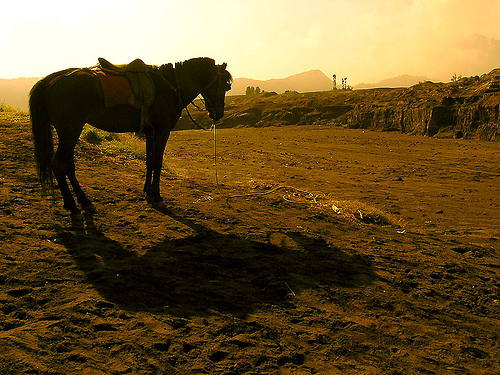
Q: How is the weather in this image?
A: It is cloudy.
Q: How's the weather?
A: It is cloudy.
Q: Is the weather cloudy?
A: Yes, it is cloudy.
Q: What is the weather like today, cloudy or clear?
A: It is cloudy.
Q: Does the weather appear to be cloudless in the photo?
A: No, it is cloudy.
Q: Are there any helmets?
A: No, there are no helmets.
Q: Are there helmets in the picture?
A: No, there are no helmets.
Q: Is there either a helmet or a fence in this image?
A: No, there are no helmets or fences.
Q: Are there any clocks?
A: No, there are no clocks.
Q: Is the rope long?
A: Yes, the rope is long.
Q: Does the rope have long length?
A: Yes, the rope is long.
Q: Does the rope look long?
A: Yes, the rope is long.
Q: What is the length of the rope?
A: The rope is long.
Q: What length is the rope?
A: The rope is long.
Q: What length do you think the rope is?
A: The rope is long.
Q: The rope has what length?
A: The rope is long.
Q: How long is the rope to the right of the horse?
A: The rope is long.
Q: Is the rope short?
A: No, the rope is long.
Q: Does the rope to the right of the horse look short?
A: No, the rope is long.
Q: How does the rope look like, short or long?
A: The rope is long.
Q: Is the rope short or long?
A: The rope is long.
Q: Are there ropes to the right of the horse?
A: Yes, there is a rope to the right of the horse.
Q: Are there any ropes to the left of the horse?
A: No, the rope is to the right of the horse.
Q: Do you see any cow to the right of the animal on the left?
A: No, there is a rope to the right of the horse.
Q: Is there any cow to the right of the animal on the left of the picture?
A: No, there is a rope to the right of the horse.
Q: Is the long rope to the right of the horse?
A: Yes, the rope is to the right of the horse.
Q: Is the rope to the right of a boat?
A: No, the rope is to the right of the horse.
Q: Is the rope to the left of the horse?
A: No, the rope is to the right of the horse.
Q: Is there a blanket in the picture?
A: Yes, there is a blanket.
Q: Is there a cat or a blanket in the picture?
A: Yes, there is a blanket.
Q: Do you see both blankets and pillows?
A: No, there is a blanket but no pillows.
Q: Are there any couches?
A: No, there are no couches.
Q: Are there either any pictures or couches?
A: No, there are no couches or pictures.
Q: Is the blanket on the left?
A: Yes, the blanket is on the left of the image.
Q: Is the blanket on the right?
A: No, the blanket is on the left of the image.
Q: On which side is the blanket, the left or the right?
A: The blanket is on the left of the image.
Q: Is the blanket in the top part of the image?
A: Yes, the blanket is in the top of the image.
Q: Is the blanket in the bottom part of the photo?
A: No, the blanket is in the top of the image.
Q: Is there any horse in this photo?
A: Yes, there is a horse.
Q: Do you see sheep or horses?
A: Yes, there is a horse.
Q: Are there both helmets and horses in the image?
A: No, there is a horse but no helmets.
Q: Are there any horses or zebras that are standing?
A: Yes, the horse is standing.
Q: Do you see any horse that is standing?
A: Yes, there is a horse that is standing.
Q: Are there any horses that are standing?
A: Yes, there is a horse that is standing.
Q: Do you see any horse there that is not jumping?
A: Yes, there is a horse that is standing .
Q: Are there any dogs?
A: No, there are no dogs.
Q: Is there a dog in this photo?
A: No, there are no dogs.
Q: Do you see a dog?
A: No, there are no dogs.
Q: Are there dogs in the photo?
A: No, there are no dogs.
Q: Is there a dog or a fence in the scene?
A: No, there are no dogs or fences.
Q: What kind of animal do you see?
A: The animal is a horse.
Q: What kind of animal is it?
A: The animal is a horse.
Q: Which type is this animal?
A: That is a horse.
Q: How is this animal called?
A: That is a horse.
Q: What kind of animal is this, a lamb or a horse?
A: That is a horse.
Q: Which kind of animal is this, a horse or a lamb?
A: That is a horse.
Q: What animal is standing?
A: The animal is a horse.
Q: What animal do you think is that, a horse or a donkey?
A: That is a horse.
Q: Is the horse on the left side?
A: Yes, the horse is on the left of the image.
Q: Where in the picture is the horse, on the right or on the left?
A: The horse is on the left of the image.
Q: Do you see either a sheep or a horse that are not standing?
A: No, there is a horse but it is standing.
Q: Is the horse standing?
A: Yes, the horse is standing.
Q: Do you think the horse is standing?
A: Yes, the horse is standing.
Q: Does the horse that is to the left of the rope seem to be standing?
A: Yes, the horse is standing.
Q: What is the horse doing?
A: The horse is standing.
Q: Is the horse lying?
A: No, the horse is standing.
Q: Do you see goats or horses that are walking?
A: No, there is a horse but it is standing.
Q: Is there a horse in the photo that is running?
A: No, there is a horse but it is standing.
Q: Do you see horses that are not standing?
A: No, there is a horse but it is standing.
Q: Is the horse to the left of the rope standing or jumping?
A: The horse is standing.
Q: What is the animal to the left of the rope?
A: The animal is a horse.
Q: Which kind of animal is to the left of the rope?
A: The animal is a horse.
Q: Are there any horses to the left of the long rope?
A: Yes, there is a horse to the left of the rope.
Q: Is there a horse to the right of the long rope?
A: No, the horse is to the left of the rope.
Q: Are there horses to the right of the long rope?
A: No, the horse is to the left of the rope.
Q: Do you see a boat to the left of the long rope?
A: No, there is a horse to the left of the rope.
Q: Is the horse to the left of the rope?
A: Yes, the horse is to the left of the rope.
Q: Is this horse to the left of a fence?
A: No, the horse is to the left of the rope.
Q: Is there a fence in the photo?
A: No, there are no fences.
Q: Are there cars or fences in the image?
A: No, there are no fences or cars.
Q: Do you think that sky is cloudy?
A: Yes, the sky is cloudy.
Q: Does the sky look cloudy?
A: Yes, the sky is cloudy.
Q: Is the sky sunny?
A: No, the sky is cloudy.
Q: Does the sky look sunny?
A: No, the sky is cloudy.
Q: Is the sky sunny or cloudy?
A: The sky is cloudy.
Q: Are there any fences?
A: No, there are no fences.